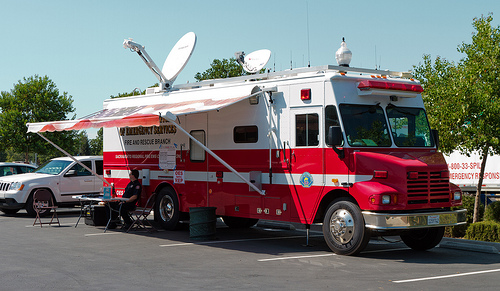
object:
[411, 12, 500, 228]
tree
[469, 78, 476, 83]
leaves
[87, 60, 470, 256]
ambulance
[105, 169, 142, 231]
man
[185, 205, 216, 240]
trash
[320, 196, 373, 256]
tire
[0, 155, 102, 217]
car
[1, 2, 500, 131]
sky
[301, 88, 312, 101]
light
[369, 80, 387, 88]
lights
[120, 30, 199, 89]
dish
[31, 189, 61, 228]
chair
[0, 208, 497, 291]
parking lot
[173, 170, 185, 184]
sign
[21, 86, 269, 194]
awning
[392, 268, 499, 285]
line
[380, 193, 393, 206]
headlight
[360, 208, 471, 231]
bumper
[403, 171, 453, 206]
grill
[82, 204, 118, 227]
container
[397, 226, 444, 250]
wheel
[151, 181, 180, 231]
wheel